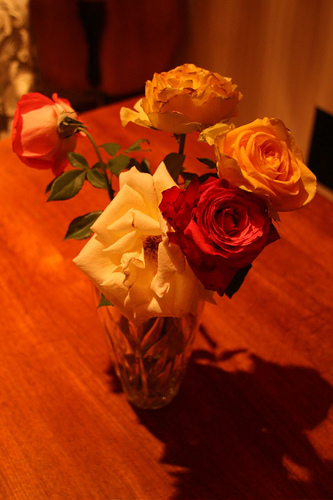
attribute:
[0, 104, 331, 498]
tabletop — wood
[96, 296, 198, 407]
crystal vase — clear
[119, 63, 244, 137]
pink rose — light pink, brown edges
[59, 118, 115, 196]
stem — green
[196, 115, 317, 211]
flower — orange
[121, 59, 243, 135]
rose — yellow, one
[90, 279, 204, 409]
vase — one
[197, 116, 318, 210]
rose — peach, browning edges, yellow, one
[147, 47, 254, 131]
rose — one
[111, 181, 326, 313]
rose — red, dark red edges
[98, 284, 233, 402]
vase — clear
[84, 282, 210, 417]
vase —  glass,  for  flower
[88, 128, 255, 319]
flowers — colored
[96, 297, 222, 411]
vase — glass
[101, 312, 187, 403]
vase — geometric, carved, glass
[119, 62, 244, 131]
rose — one, white , wilted 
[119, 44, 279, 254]
flower — white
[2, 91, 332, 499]
table — wooden, brown, dining room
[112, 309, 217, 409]
vase — one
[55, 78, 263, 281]
flowers — some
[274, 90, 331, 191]
chair — dark colored, dining room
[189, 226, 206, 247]
petal — red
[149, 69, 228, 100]
wilting — brown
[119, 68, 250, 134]
petals — rose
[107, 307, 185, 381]
vase — glass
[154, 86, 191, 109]
petal — yellow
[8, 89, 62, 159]
petal — pink